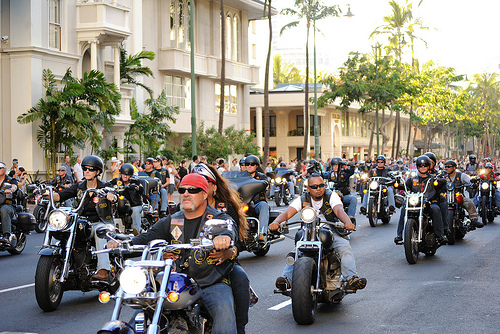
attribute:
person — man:
[146, 175, 237, 301]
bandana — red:
[177, 172, 208, 194]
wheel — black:
[32, 249, 70, 304]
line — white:
[266, 284, 297, 318]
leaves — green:
[358, 64, 407, 103]